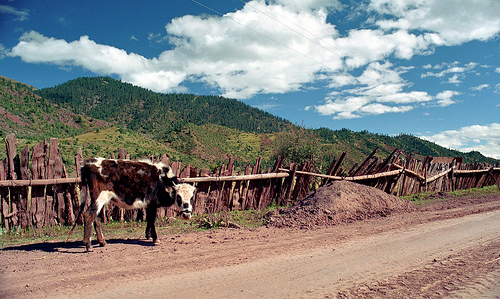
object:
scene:
[2, 3, 497, 297]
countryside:
[1, 0, 500, 295]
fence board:
[158, 156, 185, 172]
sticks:
[210, 157, 229, 204]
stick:
[4, 129, 26, 231]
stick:
[31, 138, 46, 226]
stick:
[45, 132, 59, 224]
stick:
[224, 149, 231, 213]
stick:
[251, 155, 258, 212]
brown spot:
[84, 158, 171, 206]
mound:
[273, 180, 398, 226]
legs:
[82, 194, 108, 246]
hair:
[97, 165, 112, 179]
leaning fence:
[282, 142, 415, 206]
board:
[0, 134, 500, 231]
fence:
[0, 126, 498, 227]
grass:
[89, 94, 386, 175]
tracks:
[352, 241, 484, 297]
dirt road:
[0, 195, 497, 299]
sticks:
[241, 155, 251, 211]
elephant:
[4, 131, 498, 226]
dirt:
[259, 183, 497, 278]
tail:
[69, 165, 90, 243]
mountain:
[0, 76, 500, 166]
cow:
[65, 156, 198, 254]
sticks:
[168, 155, 189, 186]